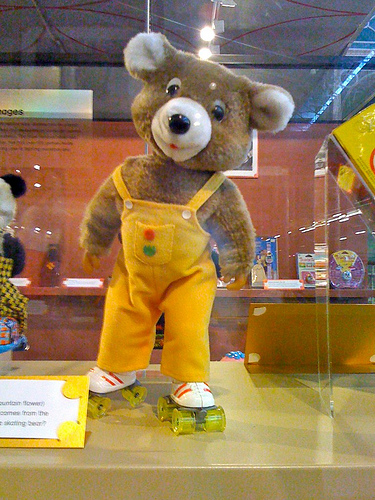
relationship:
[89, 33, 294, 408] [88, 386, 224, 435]
bear wearing skates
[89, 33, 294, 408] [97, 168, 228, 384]
bear wearing outfit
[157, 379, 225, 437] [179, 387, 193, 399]
skate has stripe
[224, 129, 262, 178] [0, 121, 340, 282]
picture hanging on wall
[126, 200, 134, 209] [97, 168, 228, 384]
button on outfit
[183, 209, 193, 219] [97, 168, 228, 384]
button on outfit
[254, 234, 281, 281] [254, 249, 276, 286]
picture of beast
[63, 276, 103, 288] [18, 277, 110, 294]
sign on top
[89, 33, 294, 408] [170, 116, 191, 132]
bear has nose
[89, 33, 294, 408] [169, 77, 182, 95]
bear has eye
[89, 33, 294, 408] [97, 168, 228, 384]
bear wears outfit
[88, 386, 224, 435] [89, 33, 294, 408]
skates on bear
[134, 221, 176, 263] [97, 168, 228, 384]
pocket on outfit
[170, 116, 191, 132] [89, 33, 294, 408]
nose of bear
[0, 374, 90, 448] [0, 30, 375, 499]
placard for display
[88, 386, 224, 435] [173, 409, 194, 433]
skates with wheel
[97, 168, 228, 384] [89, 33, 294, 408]
outfit worn by bear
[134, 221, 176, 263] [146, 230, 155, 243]
pocket with button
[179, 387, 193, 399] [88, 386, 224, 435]
stripe on skates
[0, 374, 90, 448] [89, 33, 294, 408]
placard in front of bear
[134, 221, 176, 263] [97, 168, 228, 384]
pocket in outfit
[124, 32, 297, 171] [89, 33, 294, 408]
head of bear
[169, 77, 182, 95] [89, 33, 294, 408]
eye of bear